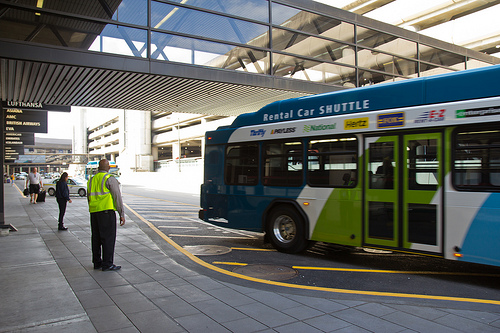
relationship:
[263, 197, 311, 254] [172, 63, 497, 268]
wheel on bus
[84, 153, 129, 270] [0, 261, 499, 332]
man on street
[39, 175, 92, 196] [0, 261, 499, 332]
car on road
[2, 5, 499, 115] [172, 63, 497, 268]
bridge by bus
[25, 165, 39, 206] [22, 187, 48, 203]
man with luggage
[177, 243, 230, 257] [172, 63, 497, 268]
cover by bus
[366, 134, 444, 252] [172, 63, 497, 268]
door on bus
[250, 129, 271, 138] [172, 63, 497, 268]
logo on bus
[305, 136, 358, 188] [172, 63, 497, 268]
window on bus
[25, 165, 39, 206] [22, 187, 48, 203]
man carrying luggage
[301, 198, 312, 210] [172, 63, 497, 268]
light on bus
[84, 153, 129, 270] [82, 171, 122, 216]
man wearing vest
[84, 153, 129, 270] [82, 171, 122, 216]
man in vest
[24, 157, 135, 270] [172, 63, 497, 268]
people by bus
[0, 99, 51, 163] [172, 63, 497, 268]
signs by bus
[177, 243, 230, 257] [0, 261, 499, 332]
cover in road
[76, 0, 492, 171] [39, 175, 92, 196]
garage for car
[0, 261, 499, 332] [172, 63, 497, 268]
street by bus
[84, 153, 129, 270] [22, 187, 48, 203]
man with luggage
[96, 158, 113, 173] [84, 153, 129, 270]
head on man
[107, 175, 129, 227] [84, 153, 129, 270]
arm of man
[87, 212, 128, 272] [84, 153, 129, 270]
legs of man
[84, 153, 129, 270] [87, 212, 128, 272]
man wearing pants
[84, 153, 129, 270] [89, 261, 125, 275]
man wearing shoes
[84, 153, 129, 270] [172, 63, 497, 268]
man by bus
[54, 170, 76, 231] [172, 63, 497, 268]
woman near bus